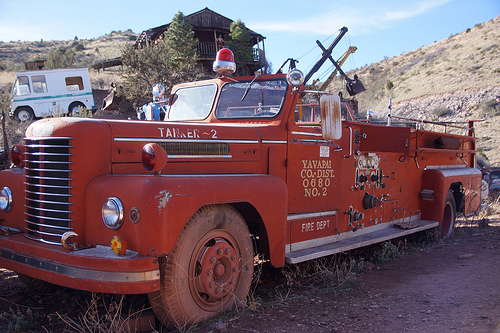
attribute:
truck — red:
[79, 49, 436, 331]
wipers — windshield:
[237, 67, 265, 109]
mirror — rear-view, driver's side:
[302, 90, 357, 155]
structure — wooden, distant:
[58, 18, 343, 136]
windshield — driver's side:
[215, 77, 284, 118]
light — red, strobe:
[214, 44, 236, 58]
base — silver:
[210, 61, 239, 75]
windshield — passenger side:
[164, 79, 289, 122]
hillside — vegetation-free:
[318, 12, 498, 151]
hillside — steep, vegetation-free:
[398, 30, 458, 91]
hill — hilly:
[307, 18, 498, 199]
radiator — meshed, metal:
[22, 135, 73, 241]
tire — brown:
[151, 207, 256, 322]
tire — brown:
[436, 190, 457, 240]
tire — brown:
[69, 100, 87, 112]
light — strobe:
[209, 42, 239, 79]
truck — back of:
[10, 34, 496, 312]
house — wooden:
[25, 41, 203, 126]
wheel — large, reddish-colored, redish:
[147, 203, 254, 330]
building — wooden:
[128, 11, 258, 72]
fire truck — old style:
[1, 26, 487, 328]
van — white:
[4, 62, 101, 124]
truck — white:
[6, 65, 99, 117]